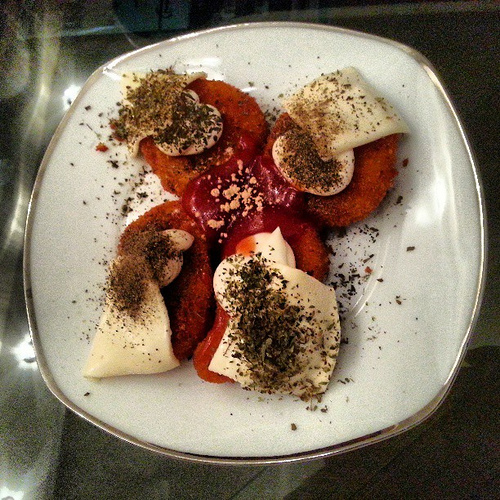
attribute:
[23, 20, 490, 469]
plate — glass like, white, flat, trimmed, mostly full, square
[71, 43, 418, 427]
food — appetizer, white, red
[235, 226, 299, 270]
cream — white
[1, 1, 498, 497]
table — grey, glass like, green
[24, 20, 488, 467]
trim — silver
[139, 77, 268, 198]
carrot — sliced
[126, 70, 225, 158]
cheese — mozzarella, white, sliced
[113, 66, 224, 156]
spices — dry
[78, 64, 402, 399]
spices — dusted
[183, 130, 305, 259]
sauce — red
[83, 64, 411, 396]
cheese — white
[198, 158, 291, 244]
cheese — grated